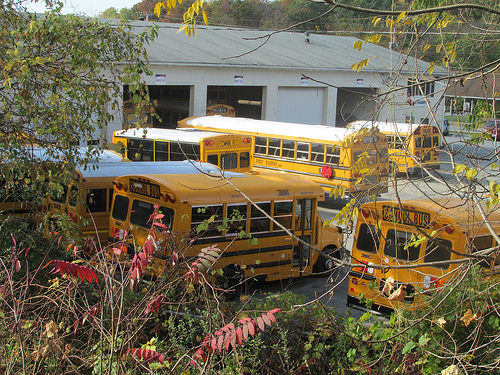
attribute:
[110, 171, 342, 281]
bus — school 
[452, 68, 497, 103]
roof — brown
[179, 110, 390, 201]
bus — school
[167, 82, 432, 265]
bus — school bus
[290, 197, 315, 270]
door — closed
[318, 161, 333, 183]
sign — red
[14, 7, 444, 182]
building — white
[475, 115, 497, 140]
van — red, parked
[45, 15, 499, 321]
school — word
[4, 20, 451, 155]
building — white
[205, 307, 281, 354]
leaf — red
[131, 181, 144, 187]
stripe — white